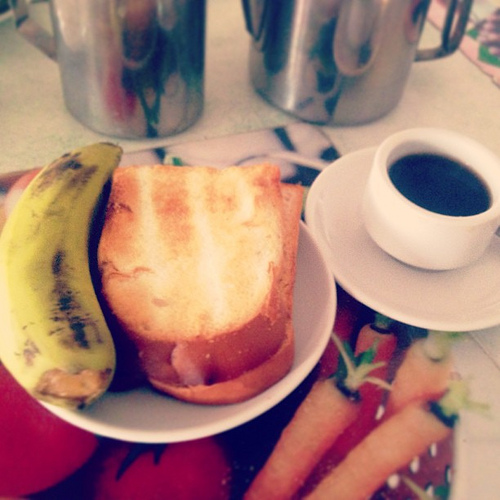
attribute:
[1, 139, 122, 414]
banana — bruised, here, yellow, dirty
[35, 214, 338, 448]
bowl — small, white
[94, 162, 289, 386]
toast — toasted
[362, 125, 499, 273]
cup — small, ceramic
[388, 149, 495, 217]
coffee — black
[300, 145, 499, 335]
saucer — here, white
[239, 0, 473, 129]
pot — metal, silver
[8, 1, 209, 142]
pot — metal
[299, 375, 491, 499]
carrot — orange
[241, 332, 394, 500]
carrot — orange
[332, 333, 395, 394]
top — green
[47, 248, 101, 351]
spot — black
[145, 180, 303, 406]
toast — here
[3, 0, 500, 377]
table — here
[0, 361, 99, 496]
tomato — here